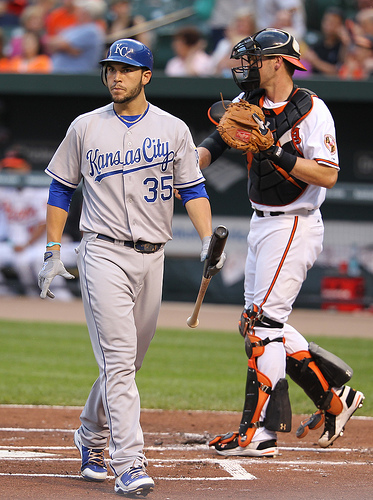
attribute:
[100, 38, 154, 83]
helmet — blue, shiny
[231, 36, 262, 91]
mask — black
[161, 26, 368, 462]
catcher — standing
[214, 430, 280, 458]
shoe — black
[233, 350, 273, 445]
shin guard — large, black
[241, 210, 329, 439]
pants — white, gray 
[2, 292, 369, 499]
baseball field — large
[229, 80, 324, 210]
chest protector — black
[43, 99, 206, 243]
jersey — light, long, grey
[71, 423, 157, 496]
cleats — white, blue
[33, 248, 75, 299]
glove — grey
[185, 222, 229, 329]
bat — black, skinny, brown, baseball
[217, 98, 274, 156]
mitt — brown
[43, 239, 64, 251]
wristband — blue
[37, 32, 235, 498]
batter — walking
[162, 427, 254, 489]
markings — white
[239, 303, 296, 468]
guards — leg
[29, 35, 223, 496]
player — baseball